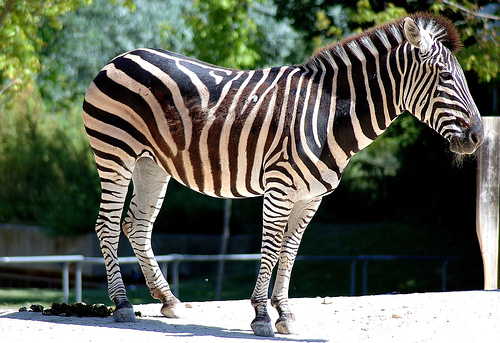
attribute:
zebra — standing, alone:
[70, 7, 484, 335]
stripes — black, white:
[202, 79, 291, 186]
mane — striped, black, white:
[308, 17, 454, 78]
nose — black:
[468, 122, 489, 149]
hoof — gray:
[271, 310, 302, 337]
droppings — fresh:
[27, 295, 113, 320]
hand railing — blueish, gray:
[5, 252, 259, 263]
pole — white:
[473, 115, 499, 292]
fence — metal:
[2, 225, 110, 276]